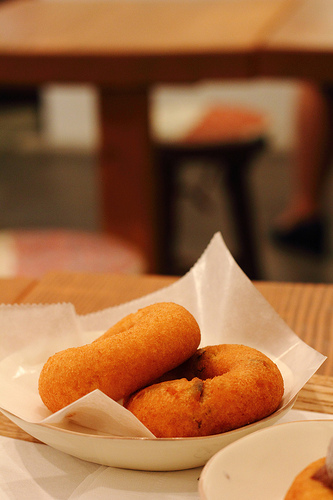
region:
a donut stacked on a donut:
[39, 300, 199, 413]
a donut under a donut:
[124, 345, 284, 436]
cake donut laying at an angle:
[39, 301, 200, 412]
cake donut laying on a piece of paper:
[122, 343, 282, 437]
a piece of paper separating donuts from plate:
[0, 233, 328, 438]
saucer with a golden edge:
[197, 416, 332, 499]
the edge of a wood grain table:
[1, 271, 331, 288]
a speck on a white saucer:
[222, 469, 235, 482]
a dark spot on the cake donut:
[191, 376, 207, 404]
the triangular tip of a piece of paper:
[201, 229, 240, 255]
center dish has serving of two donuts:
[0, 302, 296, 471]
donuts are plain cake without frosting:
[42, 301, 284, 437]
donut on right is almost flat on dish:
[122, 343, 284, 437]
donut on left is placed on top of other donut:
[39, 302, 202, 412]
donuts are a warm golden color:
[37, 301, 284, 437]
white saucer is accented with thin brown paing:
[0, 329, 298, 470]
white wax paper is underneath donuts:
[1, 230, 326, 436]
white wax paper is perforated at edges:
[0, 230, 326, 437]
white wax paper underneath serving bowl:
[0, 409, 332, 498]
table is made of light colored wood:
[0, 269, 331, 413]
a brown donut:
[215, 374, 269, 423]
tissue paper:
[198, 270, 251, 306]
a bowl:
[138, 437, 178, 464]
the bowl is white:
[110, 448, 159, 465]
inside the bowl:
[244, 451, 291, 490]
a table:
[274, 286, 313, 322]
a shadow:
[52, 462, 92, 496]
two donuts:
[53, 322, 278, 429]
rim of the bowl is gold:
[172, 436, 197, 444]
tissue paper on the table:
[2, 453, 28, 497]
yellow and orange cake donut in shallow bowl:
[35, 297, 200, 415]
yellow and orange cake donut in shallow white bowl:
[121, 335, 285, 440]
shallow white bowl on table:
[0, 317, 301, 471]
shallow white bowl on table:
[191, 409, 331, 498]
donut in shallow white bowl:
[273, 446, 331, 499]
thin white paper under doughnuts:
[0, 227, 329, 441]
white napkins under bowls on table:
[0, 401, 332, 498]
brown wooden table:
[0, 267, 332, 499]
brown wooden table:
[0, 0, 332, 88]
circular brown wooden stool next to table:
[0, 223, 154, 279]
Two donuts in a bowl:
[34, 306, 282, 433]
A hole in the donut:
[180, 356, 225, 383]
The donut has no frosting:
[38, 303, 199, 405]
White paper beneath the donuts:
[4, 240, 327, 434]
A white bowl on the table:
[0, 329, 292, 466]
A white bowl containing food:
[199, 419, 330, 498]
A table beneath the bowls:
[2, 273, 332, 497]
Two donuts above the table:
[44, 302, 281, 430]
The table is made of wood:
[3, 276, 328, 497]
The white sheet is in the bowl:
[0, 233, 326, 437]